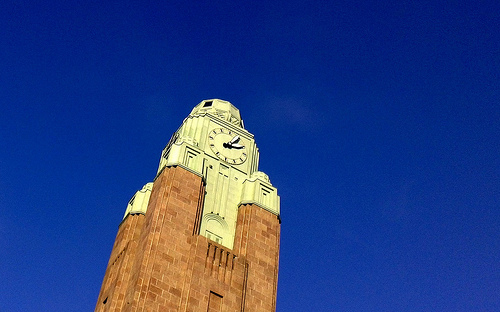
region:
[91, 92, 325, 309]
a tower clock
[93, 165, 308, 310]
a brick wall tower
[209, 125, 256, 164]
hands on face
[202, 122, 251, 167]
roman numbers on face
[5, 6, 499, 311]
a clear blue sky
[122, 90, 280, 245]
off white top for tower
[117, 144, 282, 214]
columns around tower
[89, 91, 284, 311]
a leaning tower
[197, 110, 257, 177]
a square for clock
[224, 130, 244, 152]
white hands on face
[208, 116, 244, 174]
black and white clock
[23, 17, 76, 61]
white clouds in blue sky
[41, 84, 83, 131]
white clouds in blue sky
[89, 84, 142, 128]
white clouds in blue sky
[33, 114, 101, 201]
white clouds in blue sky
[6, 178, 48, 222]
white clouds in blue sky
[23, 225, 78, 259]
white clouds in blue sky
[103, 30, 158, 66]
white clouds in blue sky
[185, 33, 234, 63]
white clouds in blue sky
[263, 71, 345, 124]
white clouds in blue sky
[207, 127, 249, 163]
Clock at the top of a tower.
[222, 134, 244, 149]
Hour and second hand on clock.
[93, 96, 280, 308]
Tower with a clock at the top of it.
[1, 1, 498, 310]
A very deep blue cloudless sky.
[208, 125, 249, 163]
Numerals on a clock face.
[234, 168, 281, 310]
Corner column of clock tower.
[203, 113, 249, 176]
Clock on tower showing time of 2:05 p.m.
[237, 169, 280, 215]
Decorative cap on top of corner of tower.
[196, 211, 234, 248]
Decorative miniature archway on clock tower.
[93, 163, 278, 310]
Base of clock tower constructed of bricks.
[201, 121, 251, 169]
clock on face of tall tower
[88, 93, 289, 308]
brick and stone tower with clock on face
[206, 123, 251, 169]
roman numers on face of tower clock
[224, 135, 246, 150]
black hands of tower clock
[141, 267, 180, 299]
red bricks on side of building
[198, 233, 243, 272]
five rectangular opening on front of tower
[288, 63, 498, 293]
patch of cloudless deep blue sky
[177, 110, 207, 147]
ridges on side of tower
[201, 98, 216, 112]
black square hole at very top of building tower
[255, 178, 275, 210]
square design on front of tower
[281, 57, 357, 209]
the sky is clear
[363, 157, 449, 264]
the sky is clear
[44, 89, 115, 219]
the sky is clear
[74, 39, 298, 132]
the sky is clear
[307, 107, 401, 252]
the sky is clear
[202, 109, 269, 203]
clock's hands are white